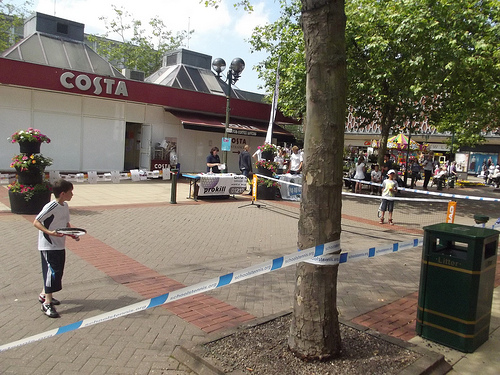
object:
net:
[247, 172, 457, 238]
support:
[443, 198, 455, 225]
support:
[236, 173, 266, 208]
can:
[417, 217, 494, 360]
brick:
[144, 271, 157, 280]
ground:
[96, 205, 262, 267]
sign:
[58, 72, 128, 97]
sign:
[231, 137, 247, 145]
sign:
[152, 163, 169, 171]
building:
[0, 12, 302, 182]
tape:
[3, 234, 425, 366]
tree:
[275, 4, 360, 364]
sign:
[220, 136, 232, 151]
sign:
[197, 172, 247, 195]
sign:
[129, 169, 140, 181]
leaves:
[250, 1, 497, 156]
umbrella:
[370, 130, 430, 152]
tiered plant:
[3, 128, 55, 211]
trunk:
[286, 0, 343, 363]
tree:
[244, 0, 500, 173]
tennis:
[389, 186, 394, 191]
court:
[29, 141, 424, 319]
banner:
[198, 176, 248, 196]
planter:
[7, 129, 52, 211]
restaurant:
[0, 12, 300, 182]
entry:
[122, 121, 140, 171]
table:
[175, 167, 253, 204]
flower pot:
[3, 127, 54, 215]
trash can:
[415, 220, 499, 354]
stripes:
[419, 256, 497, 277]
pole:
[222, 53, 232, 173]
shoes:
[40, 300, 63, 319]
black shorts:
[41, 249, 67, 296]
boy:
[32, 177, 81, 318]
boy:
[378, 169, 398, 226]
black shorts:
[380, 198, 394, 211]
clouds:
[235, 2, 269, 39]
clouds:
[36, 2, 230, 33]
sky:
[0, 0, 304, 93]